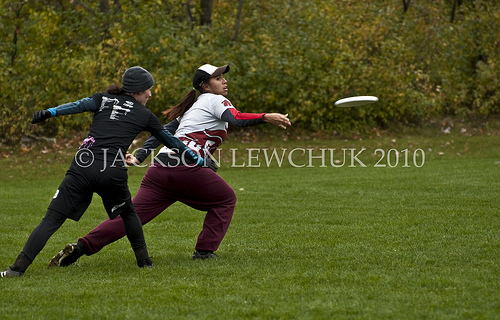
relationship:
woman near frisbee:
[0, 65, 219, 279] [330, 91, 381, 111]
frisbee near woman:
[330, 91, 381, 111] [0, 65, 219, 279]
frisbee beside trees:
[330, 91, 381, 111] [2, 2, 499, 141]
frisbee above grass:
[330, 91, 381, 111] [2, 142, 483, 318]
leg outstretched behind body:
[52, 186, 168, 266] [142, 95, 287, 187]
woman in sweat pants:
[48, 64, 293, 265] [78, 153, 237, 256]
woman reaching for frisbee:
[48, 64, 293, 265] [334, 95, 379, 107]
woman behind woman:
[6, 59, 212, 278] [48, 64, 293, 265]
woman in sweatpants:
[48, 64, 293, 265] [47, 159, 236, 267]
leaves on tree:
[1, 3, 498, 123] [1, 0, 237, 148]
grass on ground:
[2, 142, 483, 318] [1, 132, 497, 317]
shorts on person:
[46, 160, 132, 219] [1, 62, 203, 277]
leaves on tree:
[251, 43, 300, 84] [138, 2, 440, 139]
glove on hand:
[31, 110, 51, 124] [29, 105, 53, 123]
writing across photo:
[283, 140, 431, 174] [0, 0, 484, 318]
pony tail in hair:
[161, 87, 197, 120] [158, 76, 217, 124]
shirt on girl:
[153, 90, 242, 154] [47, 55, 296, 275]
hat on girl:
[191, 59, 232, 87] [47, 55, 296, 275]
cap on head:
[118, 60, 157, 90] [117, 60, 157, 111]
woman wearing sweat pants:
[0, 63, 291, 278] [68, 151, 240, 256]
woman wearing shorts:
[6, 59, 212, 278] [47, 155, 133, 222]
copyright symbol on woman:
[72, 141, 98, 175] [6, 59, 212, 278]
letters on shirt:
[96, 94, 137, 129] [29, 92, 195, 176]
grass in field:
[2, 142, 483, 318] [3, 145, 483, 318]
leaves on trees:
[248, 27, 359, 76] [4, 2, 483, 156]